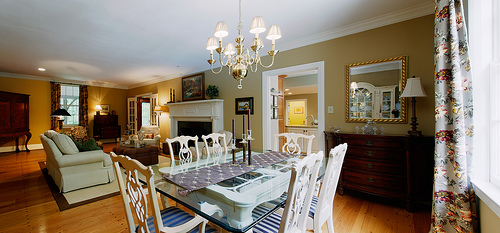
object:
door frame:
[276, 72, 320, 156]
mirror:
[348, 60, 398, 118]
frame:
[344, 55, 410, 123]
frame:
[179, 72, 204, 99]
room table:
[125, 148, 331, 227]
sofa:
[36, 129, 114, 192]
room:
[0, 1, 498, 233]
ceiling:
[0, 0, 440, 90]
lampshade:
[396, 77, 431, 98]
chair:
[109, 150, 211, 232]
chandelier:
[205, 0, 282, 91]